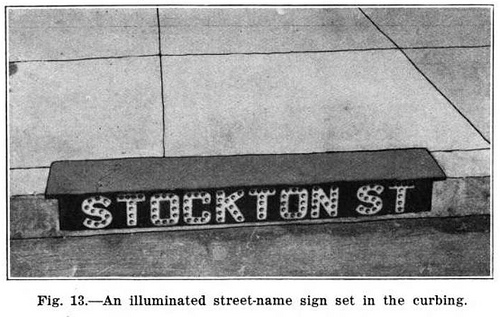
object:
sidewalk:
[10, 5, 492, 241]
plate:
[46, 147, 444, 233]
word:
[83, 182, 344, 229]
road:
[10, 212, 490, 279]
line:
[8, 54, 147, 65]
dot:
[98, 209, 105, 214]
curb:
[9, 161, 493, 239]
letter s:
[81, 194, 114, 229]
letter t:
[117, 191, 145, 227]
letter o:
[149, 190, 181, 228]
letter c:
[183, 189, 213, 225]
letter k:
[215, 188, 246, 225]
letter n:
[310, 183, 339, 219]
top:
[44, 147, 434, 198]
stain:
[197, 223, 271, 245]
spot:
[274, 9, 290, 16]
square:
[159, 46, 491, 159]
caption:
[37, 291, 468, 309]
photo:
[6, 2, 496, 281]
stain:
[7, 60, 19, 76]